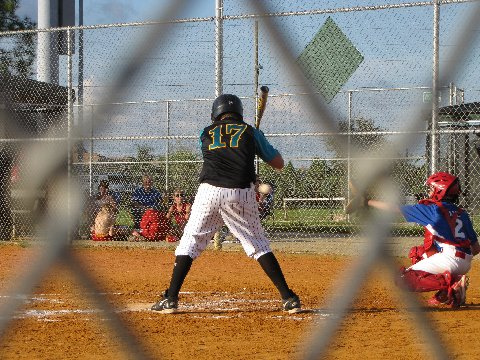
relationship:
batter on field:
[151, 92, 303, 316] [1, 243, 476, 358]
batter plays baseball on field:
[151, 92, 303, 316] [1, 243, 476, 358]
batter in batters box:
[151, 92, 303, 316] [26, 242, 318, 346]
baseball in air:
[252, 177, 275, 204] [289, 27, 412, 157]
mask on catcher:
[402, 169, 465, 204] [381, 158, 477, 304]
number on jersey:
[216, 126, 313, 176] [189, 103, 312, 212]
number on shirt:
[208, 123, 248, 150] [197, 121, 273, 186]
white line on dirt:
[1, 290, 334, 321] [0, 246, 480, 359]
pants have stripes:
[175, 183, 272, 253] [169, 182, 201, 253]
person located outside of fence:
[165, 191, 192, 240] [121, 51, 424, 230]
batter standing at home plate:
[143, 87, 307, 319] [126, 292, 307, 322]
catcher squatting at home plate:
[344, 170, 479, 313] [125, 298, 174, 316]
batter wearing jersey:
[151, 92, 303, 316] [200, 121, 257, 187]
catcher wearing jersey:
[344, 171, 480, 312] [400, 202, 477, 250]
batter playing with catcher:
[151, 92, 303, 316] [344, 171, 480, 312]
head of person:
[95, 179, 110, 196] [79, 170, 130, 209]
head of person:
[166, 186, 190, 207] [161, 186, 198, 244]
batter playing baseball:
[151, 92, 303, 316] [141, 93, 322, 337]